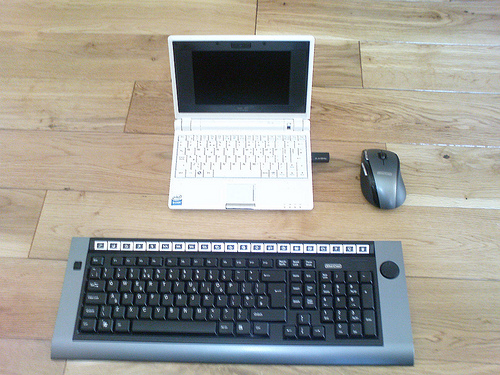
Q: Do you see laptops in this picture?
A: Yes, there is a laptop.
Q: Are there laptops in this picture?
A: Yes, there is a laptop.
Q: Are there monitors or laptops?
A: Yes, there is a laptop.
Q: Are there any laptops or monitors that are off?
A: Yes, the laptop is off.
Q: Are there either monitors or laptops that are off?
A: Yes, the laptop is off.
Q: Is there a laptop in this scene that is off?
A: Yes, there is a laptop that is off.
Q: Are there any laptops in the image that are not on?
A: Yes, there is a laptop that is off.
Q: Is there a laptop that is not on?
A: Yes, there is a laptop that is off.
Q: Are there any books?
A: No, there are no books.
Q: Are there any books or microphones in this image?
A: No, there are no books or microphones.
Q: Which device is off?
A: The device is a laptop.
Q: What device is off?
A: The device is a laptop.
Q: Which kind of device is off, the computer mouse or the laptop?
A: The laptop is off.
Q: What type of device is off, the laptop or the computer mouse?
A: The laptop is off.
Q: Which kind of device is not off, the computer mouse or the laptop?
A: The computer mouse is not off.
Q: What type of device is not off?
A: The device is a computer mouse.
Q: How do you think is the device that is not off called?
A: The device is a computer mouse.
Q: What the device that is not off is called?
A: The device is a computer mouse.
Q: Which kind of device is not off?
A: The device is a computer mouse.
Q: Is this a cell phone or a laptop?
A: This is a laptop.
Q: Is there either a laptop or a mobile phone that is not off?
A: No, there is a laptop but it is off.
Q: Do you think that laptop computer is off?
A: Yes, the laptop computer is off.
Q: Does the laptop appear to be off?
A: Yes, the laptop is off.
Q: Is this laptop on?
A: No, the laptop is off.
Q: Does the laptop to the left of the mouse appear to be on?
A: No, the laptop computer is off.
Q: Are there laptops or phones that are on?
A: No, there is a laptop but it is off.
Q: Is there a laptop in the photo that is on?
A: No, there is a laptop but it is off.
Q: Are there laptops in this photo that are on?
A: No, there is a laptop but it is off.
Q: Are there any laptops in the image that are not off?
A: No, there is a laptop but it is off.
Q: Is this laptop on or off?
A: The laptop is off.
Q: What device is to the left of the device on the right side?
A: The device is a laptop.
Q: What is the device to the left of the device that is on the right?
A: The device is a laptop.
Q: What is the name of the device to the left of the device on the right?
A: The device is a laptop.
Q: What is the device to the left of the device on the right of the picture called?
A: The device is a laptop.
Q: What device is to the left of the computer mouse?
A: The device is a laptop.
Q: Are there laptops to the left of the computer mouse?
A: Yes, there is a laptop to the left of the computer mouse.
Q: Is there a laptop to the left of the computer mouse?
A: Yes, there is a laptop to the left of the computer mouse.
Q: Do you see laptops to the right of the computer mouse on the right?
A: No, the laptop is to the left of the computer mouse.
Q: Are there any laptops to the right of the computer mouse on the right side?
A: No, the laptop is to the left of the computer mouse.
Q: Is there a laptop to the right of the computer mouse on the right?
A: No, the laptop is to the left of the computer mouse.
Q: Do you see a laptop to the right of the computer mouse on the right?
A: No, the laptop is to the left of the computer mouse.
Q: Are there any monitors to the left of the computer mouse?
A: No, there is a laptop to the left of the computer mouse.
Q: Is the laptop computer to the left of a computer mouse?
A: Yes, the laptop computer is to the left of a computer mouse.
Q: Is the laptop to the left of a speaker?
A: No, the laptop is to the left of a computer mouse.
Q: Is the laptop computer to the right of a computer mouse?
A: No, the laptop computer is to the left of a computer mouse.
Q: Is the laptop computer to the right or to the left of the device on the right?
A: The laptop computer is to the left of the computer mouse.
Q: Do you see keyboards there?
A: Yes, there is a keyboard.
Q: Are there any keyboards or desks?
A: Yes, there is a keyboard.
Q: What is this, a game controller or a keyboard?
A: This is a keyboard.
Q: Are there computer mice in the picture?
A: Yes, there is a computer mouse.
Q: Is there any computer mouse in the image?
A: Yes, there is a computer mouse.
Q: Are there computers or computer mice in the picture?
A: Yes, there is a computer mouse.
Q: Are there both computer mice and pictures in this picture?
A: No, there is a computer mouse but no pictures.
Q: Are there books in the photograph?
A: No, there are no books.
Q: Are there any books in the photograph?
A: No, there are no books.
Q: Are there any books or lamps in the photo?
A: No, there are no books or lamps.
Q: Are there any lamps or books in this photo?
A: No, there are no books or lamps.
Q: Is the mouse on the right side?
A: Yes, the mouse is on the right of the image.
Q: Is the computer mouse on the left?
A: No, the computer mouse is on the right of the image.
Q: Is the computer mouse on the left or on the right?
A: The computer mouse is on the right of the image.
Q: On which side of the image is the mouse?
A: The mouse is on the right of the image.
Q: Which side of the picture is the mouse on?
A: The mouse is on the right of the image.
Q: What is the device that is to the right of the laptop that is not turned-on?
A: The device is a computer mouse.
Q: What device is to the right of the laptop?
A: The device is a computer mouse.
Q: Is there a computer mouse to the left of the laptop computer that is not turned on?
A: No, the computer mouse is to the right of the laptop.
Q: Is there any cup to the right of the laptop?
A: No, there is a computer mouse to the right of the laptop.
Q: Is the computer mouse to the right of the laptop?
A: Yes, the computer mouse is to the right of the laptop.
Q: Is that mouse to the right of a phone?
A: No, the mouse is to the right of the laptop.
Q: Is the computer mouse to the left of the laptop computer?
A: No, the computer mouse is to the right of the laptop computer.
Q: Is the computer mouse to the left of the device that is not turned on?
A: No, the computer mouse is to the right of the laptop computer.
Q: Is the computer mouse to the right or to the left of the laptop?
A: The computer mouse is to the right of the laptop.